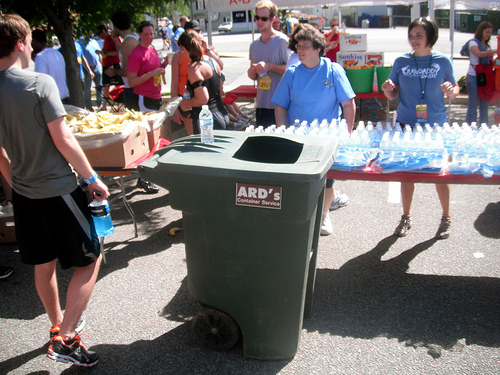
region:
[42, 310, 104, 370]
Man is wearing shoes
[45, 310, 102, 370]
Man is wearing black and orange shoes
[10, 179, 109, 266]
Man is wearing shorts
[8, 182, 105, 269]
Man is wearing black and gray shorts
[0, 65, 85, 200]
Man is wearing a shirt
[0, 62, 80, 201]
Man is wearing a gray shirt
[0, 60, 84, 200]
Man is wearing a t-shirt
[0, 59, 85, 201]
Man is wearing a gray t-shirt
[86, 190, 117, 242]
Man is holding a bottle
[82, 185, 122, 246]
Man is holding a blue bottle of sports drink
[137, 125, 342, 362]
A large plastic recycling bin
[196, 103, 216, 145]
A bottle of water on the bin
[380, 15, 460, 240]
A woman standing behind the table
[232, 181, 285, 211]
A company name on the bin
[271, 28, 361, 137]
A woman in a blue shirt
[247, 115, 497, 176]
Packages of water bottles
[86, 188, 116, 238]
A container of blue liquid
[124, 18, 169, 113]
A woman in a pink shirt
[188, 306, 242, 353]
A black wheel on the bin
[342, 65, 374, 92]
A large green pail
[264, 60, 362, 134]
the shirt is blue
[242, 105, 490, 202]
water bottles on the table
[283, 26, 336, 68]
the head of a woman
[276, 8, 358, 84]
the hair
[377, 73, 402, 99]
the hand of a woman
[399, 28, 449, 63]
the neck of a woman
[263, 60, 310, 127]
the arm of a woman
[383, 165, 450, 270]
the legs of a woman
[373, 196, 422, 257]
the foot of a woman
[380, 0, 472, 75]
the face of a woman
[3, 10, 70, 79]
the head of a man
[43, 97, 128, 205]
the arm of a man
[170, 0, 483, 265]
people standing at table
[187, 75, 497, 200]
table top filled with bottled water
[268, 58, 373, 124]
woman wearing blue shirt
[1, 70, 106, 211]
man wearing grey shirt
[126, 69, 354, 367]
green trash container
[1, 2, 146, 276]
man holding blue bottle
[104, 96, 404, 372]
whole on top of trash can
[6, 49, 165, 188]
box of items on table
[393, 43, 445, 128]
woman wearing lanyard around neck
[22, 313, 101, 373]
man wearing black and orange shoes